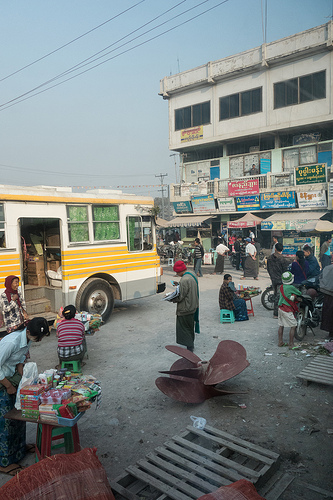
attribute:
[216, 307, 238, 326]
stool — blue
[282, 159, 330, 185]
sign — green and yellow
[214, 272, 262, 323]
girl — sitting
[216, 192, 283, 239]
awning — red and white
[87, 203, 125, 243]
curtains — green and white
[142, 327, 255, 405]
propeller — rusted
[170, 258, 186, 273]
hat — red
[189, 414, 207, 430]
item — blue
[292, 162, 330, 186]
sign — rectangular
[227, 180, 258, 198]
sign — rectangular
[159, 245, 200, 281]
hat — red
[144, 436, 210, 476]
pallet — wood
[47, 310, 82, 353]
shirt — stripes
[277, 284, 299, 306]
shirt — green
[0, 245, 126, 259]
stripe — yellow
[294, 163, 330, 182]
sign — rectangular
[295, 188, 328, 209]
sign — rectangular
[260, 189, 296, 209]
sign — rectangular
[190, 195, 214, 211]
sign — rectangular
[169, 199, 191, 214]
sign — rectangular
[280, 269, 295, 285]
hat — green and white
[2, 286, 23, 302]
scarf — red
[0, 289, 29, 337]
shirt — checkered